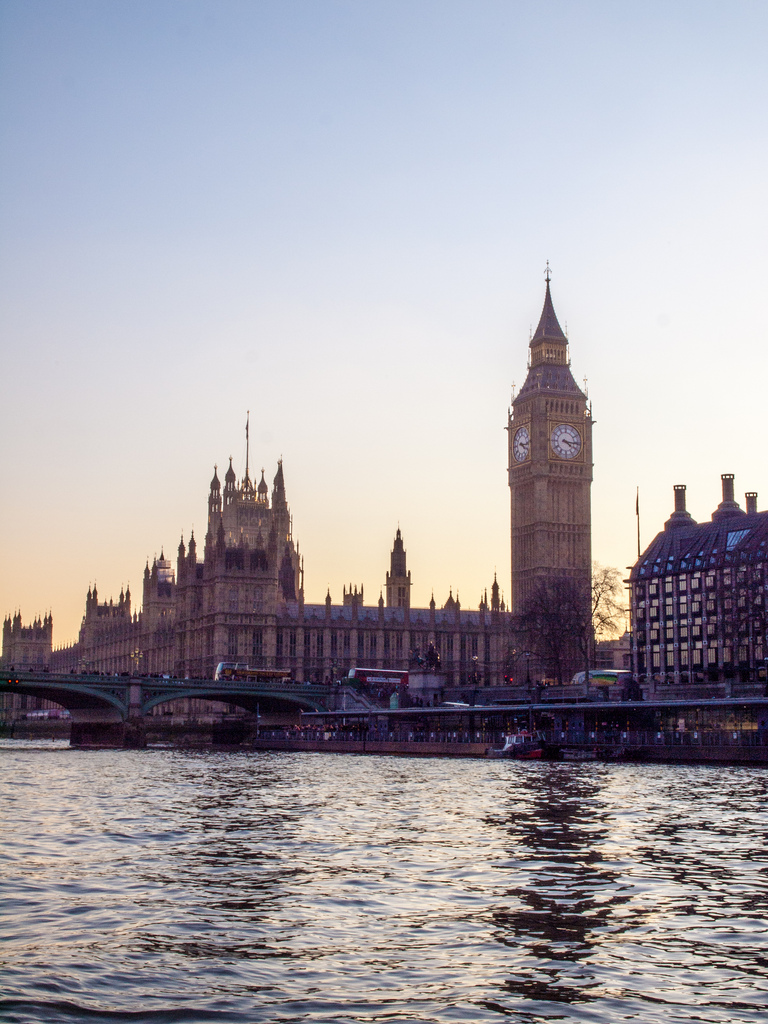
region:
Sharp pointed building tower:
[530, 242, 572, 334]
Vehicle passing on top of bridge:
[201, 649, 304, 689]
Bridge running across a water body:
[4, 671, 371, 715]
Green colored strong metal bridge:
[103, 679, 166, 709]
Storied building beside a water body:
[634, 544, 765, 688]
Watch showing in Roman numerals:
[541, 417, 588, 469]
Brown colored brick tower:
[506, 474, 595, 589]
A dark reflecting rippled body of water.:
[2, 738, 766, 1022]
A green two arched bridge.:
[1, 664, 336, 749]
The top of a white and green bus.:
[569, 666, 631, 682]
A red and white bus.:
[344, 668, 408, 687]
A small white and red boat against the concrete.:
[482, 731, 566, 762]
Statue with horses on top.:
[403, 637, 442, 671]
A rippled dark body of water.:
[1, 737, 764, 1023]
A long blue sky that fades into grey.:
[0, 2, 766, 575]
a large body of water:
[0, 737, 766, 1018]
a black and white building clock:
[548, 417, 586, 457]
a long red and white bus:
[346, 665, 410, 683]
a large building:
[625, 478, 766, 688]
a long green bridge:
[1, 672, 331, 742]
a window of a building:
[675, 569, 692, 589]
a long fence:
[580, 725, 762, 744]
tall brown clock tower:
[491, 294, 601, 628]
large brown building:
[70, 426, 455, 658]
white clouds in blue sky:
[30, 212, 103, 278]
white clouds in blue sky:
[271, 256, 342, 318]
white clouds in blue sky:
[127, 498, 173, 536]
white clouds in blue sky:
[50, 350, 96, 394]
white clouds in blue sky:
[201, 193, 297, 281]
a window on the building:
[712, 612, 728, 641]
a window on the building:
[669, 646, 671, 648]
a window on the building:
[669, 653, 708, 668]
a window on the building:
[737, 629, 764, 666]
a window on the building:
[662, 625, 709, 661]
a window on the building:
[676, 577, 692, 600]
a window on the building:
[675, 563, 709, 616]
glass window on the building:
[646, 576, 655, 586]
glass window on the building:
[659, 574, 669, 590]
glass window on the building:
[674, 572, 686, 590]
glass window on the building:
[690, 565, 699, 591]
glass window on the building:
[698, 565, 713, 589]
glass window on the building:
[633, 595, 646, 621]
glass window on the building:
[646, 597, 658, 620]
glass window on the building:
[660, 594, 674, 612]